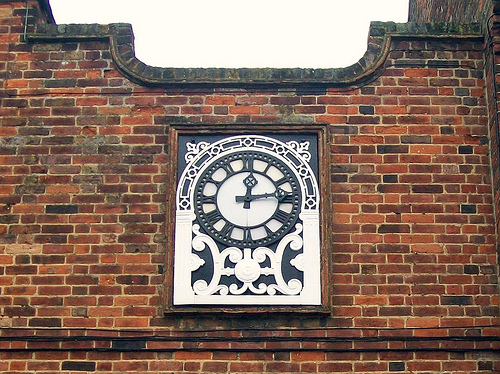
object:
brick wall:
[335, 84, 494, 102]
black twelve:
[241, 156, 255, 171]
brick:
[346, 179, 489, 287]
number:
[221, 162, 234, 175]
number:
[263, 162, 272, 173]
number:
[275, 176, 288, 185]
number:
[273, 209, 289, 223]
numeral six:
[243, 227, 254, 242]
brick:
[333, 295, 496, 326]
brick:
[324, 349, 499, 371]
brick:
[0, 351, 230, 371]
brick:
[0, 300, 162, 326]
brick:
[331, 124, 482, 182]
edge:
[227, 257, 252, 278]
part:
[240, 255, 257, 267]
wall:
[18, 351, 448, 372]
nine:
[200, 194, 217, 204]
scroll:
[191, 223, 304, 294]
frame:
[160, 118, 333, 312]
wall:
[305, 58, 472, 323]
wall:
[3, 97, 107, 374]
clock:
[191, 151, 302, 249]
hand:
[253, 187, 294, 202]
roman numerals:
[272, 175, 292, 188]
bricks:
[206, 84, 327, 94]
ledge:
[2, 315, 500, 360]